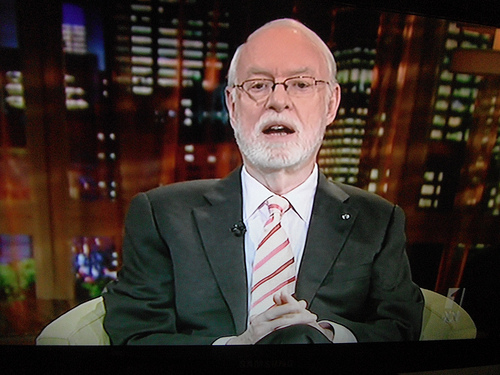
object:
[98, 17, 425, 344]
man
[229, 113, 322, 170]
beard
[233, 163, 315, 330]
collared shirt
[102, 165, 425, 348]
suit jacket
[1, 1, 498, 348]
background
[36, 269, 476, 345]
chair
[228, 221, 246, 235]
microphone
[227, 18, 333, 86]
hair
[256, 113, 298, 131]
mustache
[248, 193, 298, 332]
tie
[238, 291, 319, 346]
hands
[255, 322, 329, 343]
knee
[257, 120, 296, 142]
mouth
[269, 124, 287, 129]
upper teeth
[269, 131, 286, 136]
lower teeth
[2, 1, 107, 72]
sky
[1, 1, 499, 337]
buildings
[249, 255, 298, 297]
stripes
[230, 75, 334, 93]
glasses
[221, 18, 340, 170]
head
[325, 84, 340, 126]
ear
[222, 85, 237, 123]
ear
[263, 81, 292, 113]
nose